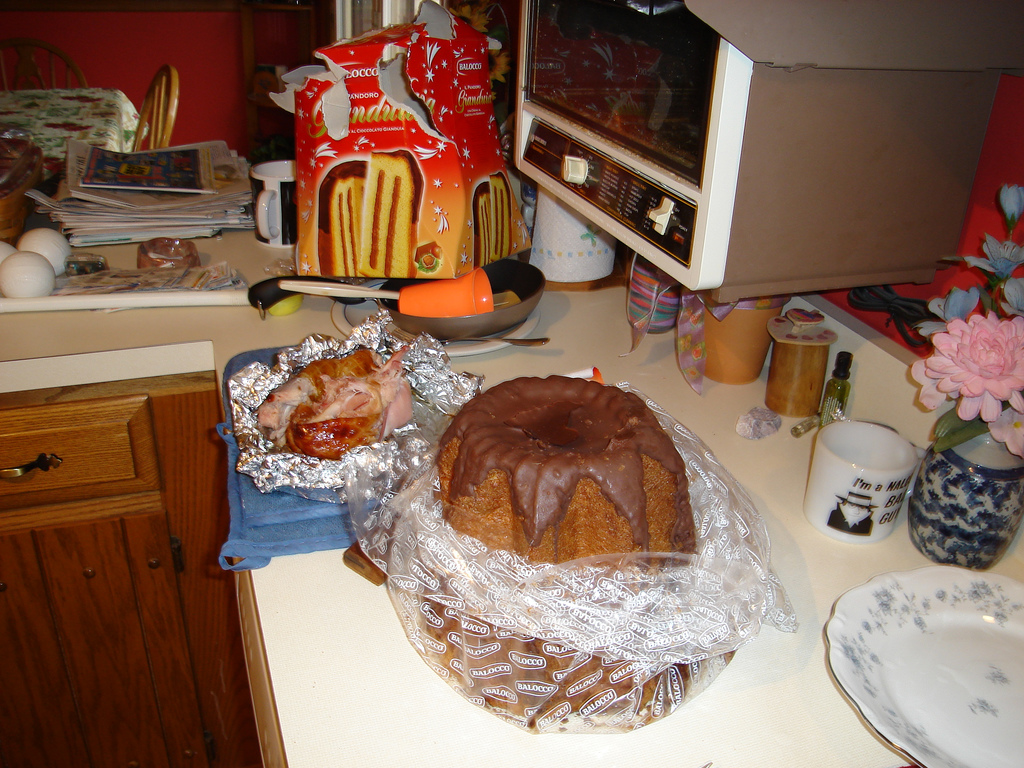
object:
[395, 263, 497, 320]
cup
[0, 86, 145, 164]
table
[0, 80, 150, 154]
tablecloth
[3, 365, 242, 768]
counter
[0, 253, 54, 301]
egg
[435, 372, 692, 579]
food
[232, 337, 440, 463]
food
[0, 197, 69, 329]
food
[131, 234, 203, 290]
food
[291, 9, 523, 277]
food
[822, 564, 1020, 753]
plate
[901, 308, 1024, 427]
flowers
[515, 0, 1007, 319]
microwave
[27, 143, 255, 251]
newspaper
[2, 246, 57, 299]
ball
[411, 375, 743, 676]
bundt cake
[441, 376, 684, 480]
frosting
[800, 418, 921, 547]
mug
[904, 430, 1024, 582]
vase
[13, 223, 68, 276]
eggs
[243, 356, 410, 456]
turkey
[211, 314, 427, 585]
oven mitts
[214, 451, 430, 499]
foil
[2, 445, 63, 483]
handle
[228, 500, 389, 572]
towel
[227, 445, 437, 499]
aluminum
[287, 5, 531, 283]
box